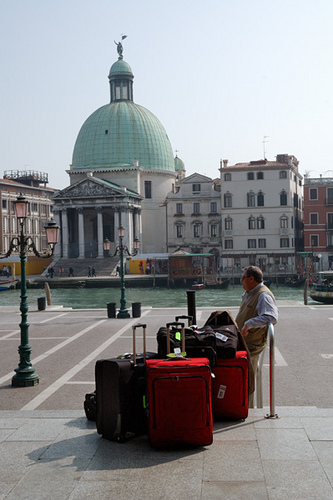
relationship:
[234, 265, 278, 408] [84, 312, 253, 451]
body by luggage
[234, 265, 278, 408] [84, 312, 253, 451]
body and h luggage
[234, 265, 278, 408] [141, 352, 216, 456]
body waiting with h luggage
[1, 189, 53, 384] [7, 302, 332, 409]
light pole on street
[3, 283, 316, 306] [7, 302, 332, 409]
water near street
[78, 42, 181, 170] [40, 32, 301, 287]
roof of building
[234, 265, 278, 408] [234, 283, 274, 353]
body has on sweater vest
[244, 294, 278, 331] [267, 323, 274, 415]
arm leaning on metal pole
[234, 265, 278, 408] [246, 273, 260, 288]
body has an ear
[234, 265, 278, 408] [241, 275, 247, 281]
body has an eye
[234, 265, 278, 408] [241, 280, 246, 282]
body has nose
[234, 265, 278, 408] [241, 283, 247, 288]
body has mouth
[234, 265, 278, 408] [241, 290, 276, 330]
body has arm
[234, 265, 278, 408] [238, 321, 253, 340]
body has hand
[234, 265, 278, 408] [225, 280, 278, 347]
body has body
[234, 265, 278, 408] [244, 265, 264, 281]
body has hair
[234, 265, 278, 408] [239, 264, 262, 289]
body has head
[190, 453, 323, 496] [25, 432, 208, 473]
ground has shadow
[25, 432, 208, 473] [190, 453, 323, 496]
shadow on ground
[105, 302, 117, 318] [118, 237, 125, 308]
container next to pole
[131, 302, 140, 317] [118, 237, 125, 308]
container next to pole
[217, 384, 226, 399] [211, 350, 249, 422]
tag on bag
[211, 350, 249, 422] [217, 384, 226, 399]
bag has tag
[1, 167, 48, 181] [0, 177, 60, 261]
balcony on top of building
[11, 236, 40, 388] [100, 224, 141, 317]
green pole has street lamp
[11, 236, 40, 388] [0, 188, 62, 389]
green pole has street lamp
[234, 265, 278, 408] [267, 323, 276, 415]
body leaning on metal rail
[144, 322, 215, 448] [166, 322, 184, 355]
bag has up handle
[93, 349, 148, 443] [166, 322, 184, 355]
luggage has up handle